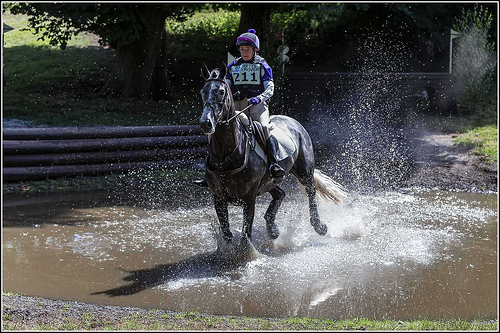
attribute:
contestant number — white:
[223, 65, 295, 96]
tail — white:
[313, 168, 340, 204]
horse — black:
[192, 75, 349, 260]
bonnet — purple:
[232, 26, 261, 50]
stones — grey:
[5, 296, 154, 330]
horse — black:
[196, 59, 348, 265]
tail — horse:
[299, 162, 349, 204]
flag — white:
[446, 27, 460, 77]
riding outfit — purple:
[189, 46, 316, 118]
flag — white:
[445, 28, 468, 76]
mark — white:
[203, 80, 219, 110]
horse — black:
[170, 57, 373, 255]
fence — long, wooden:
[3, 120, 209, 180]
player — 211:
[221, 29, 286, 181]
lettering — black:
[233, 72, 260, 79]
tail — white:
[294, 155, 354, 208]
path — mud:
[388, 109, 483, 199]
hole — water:
[10, 191, 484, 325]